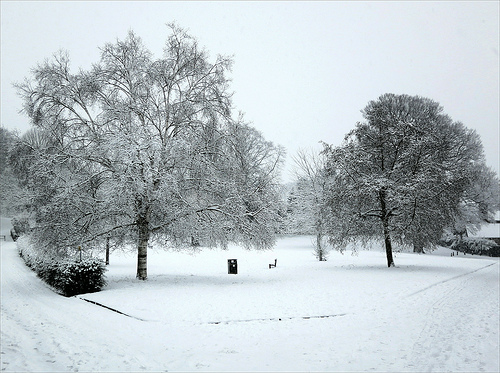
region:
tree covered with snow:
[313, 86, 497, 270]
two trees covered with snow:
[20, 23, 488, 285]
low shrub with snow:
[18, 239, 106, 296]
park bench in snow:
[266, 255, 282, 270]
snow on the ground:
[8, 285, 498, 369]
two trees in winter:
[17, 14, 495, 270]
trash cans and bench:
[223, 252, 285, 277]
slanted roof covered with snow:
[458, 211, 498, 248]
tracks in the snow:
[405, 273, 498, 369]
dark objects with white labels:
[225, 256, 240, 276]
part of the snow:
[433, 272, 452, 294]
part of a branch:
[192, 206, 207, 220]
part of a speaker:
[226, 262, 234, 278]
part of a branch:
[380, 208, 390, 219]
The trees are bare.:
[8, 49, 493, 239]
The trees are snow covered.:
[8, 34, 499, 298]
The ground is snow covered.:
[18, 238, 498, 363]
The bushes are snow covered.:
[14, 225, 103, 289]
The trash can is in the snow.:
[225, 253, 238, 275]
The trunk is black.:
[124, 193, 154, 293]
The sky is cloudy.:
[8, 3, 499, 150]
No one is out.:
[6, 0, 493, 365]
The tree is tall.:
[10, 20, 287, 321]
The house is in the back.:
[454, 208, 499, 258]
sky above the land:
[276, 15, 353, 62]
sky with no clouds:
[260, 10, 370, 75]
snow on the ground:
[290, 270, 345, 305]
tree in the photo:
[345, 155, 435, 245]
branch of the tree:
[370, 205, 405, 270]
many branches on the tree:
[85, 100, 215, 215]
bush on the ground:
[15, 225, 120, 295]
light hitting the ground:
[180, 280, 260, 340]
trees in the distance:
[270, 155, 340, 226]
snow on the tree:
[71, 107, 203, 216]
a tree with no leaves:
[319, 96, 476, 284]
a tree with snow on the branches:
[337, 81, 495, 283]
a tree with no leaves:
[7, 35, 277, 286]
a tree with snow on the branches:
[17, 45, 277, 287]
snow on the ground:
[157, 295, 473, 360]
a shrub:
[26, 210, 107, 304]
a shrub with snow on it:
[14, 218, 107, 295]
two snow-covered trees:
[22, 35, 492, 289]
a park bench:
[260, 258, 279, 272]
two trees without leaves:
[27, 32, 482, 277]